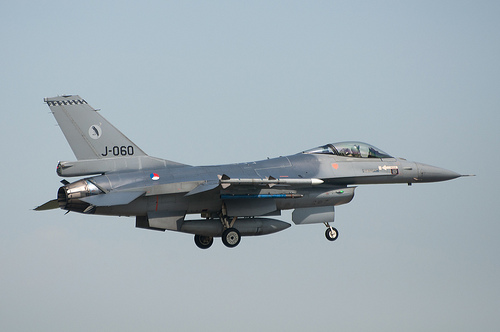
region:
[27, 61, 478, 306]
a gray plane is in the photo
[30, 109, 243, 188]
numbers are on a plane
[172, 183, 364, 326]
the wheels are still showing on a plane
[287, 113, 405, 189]
a pilot is in the plane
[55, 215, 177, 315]
the sky is gray and clear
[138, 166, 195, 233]
red, white, and blue, is on the plane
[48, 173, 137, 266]
the tail of the plane is silver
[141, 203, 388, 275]
A missle is on the bottom of the plane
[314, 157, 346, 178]
an orange symbol is on the plane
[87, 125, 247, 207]
J-060 is on the tail of the plane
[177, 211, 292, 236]
large gray warhead between rear wheels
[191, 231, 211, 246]
rear left tire on side of warhead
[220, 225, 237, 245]
rear right tire on side on warhead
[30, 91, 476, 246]
gray fighter jet flying in the sky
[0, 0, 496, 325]
bluish gray hazy sky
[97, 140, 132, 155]
black id number on tail wing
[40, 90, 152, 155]
gray tail wing on fighter jet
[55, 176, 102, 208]
silver plane engine under tail wing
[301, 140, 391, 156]
glass windshield on fighter jet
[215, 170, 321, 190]
long skinny white tipped rocket on wing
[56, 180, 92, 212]
engine on a jet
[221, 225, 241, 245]
wheel on a jet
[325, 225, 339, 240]
wheel on a jet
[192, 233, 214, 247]
wheel on a jet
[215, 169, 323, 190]
missile on a jet wing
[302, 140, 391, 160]
cockpit of a jet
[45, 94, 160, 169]
tail of a jetplane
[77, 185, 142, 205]
rear wing on a plane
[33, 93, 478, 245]
a jet in the air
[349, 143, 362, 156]
pilot in the cockpit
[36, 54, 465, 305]
Grey jet in the sky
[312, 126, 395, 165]
Small window of a jet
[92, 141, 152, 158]
Black lettering on plane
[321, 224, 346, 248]
Black and white wheel of plane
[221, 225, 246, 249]
Black and white wheel of plane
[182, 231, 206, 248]
Black and white wheel of plane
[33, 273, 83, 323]
Small part of the sky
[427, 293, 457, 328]
Small part of the sky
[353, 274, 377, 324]
Small part of the sky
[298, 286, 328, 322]
Small part of the sky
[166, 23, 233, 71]
this is the sky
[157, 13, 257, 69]
the sky is blue in color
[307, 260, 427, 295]
the sky has clouds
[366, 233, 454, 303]
the clouds are white in color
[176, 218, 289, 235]
this is a missile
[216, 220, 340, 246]
these are some wheels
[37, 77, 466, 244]
this is a jet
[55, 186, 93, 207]
this is the exhaust pipe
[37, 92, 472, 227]
the jet is in the air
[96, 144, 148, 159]
these are some writings